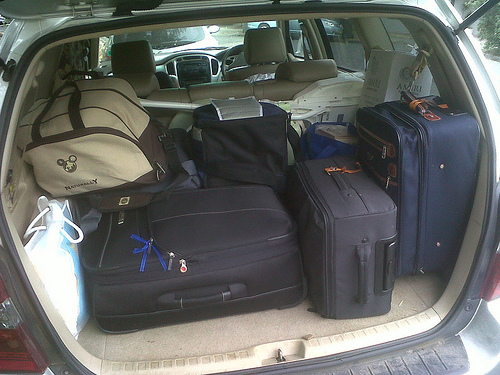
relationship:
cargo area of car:
[1, 0, 488, 375] [0, 0, 500, 375]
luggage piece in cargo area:
[351, 90, 483, 278] [1, 0, 488, 375]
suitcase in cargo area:
[284, 155, 401, 325] [1, 0, 488, 375]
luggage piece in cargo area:
[81, 180, 313, 331] [1, 0, 488, 375]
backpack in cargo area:
[12, 69, 188, 215] [1, 0, 488, 375]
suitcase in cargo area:
[181, 94, 294, 196] [1, 0, 488, 375]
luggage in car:
[17, 73, 482, 337] [2, 0, 497, 370]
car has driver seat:
[2, 0, 497, 370] [104, 35, 182, 95]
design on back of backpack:
[56, 149, 76, 175] [18, 63, 175, 207]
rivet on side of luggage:
[438, 162, 443, 171] [347, 91, 480, 281]